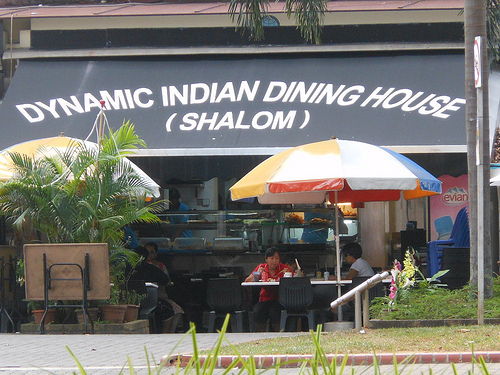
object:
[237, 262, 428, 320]
table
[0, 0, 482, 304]
restaurant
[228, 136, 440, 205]
umbrella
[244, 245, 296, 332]
woman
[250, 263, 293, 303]
shirt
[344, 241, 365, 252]
top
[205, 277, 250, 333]
chair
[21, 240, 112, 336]
table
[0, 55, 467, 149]
sign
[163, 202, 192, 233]
uniform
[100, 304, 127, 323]
pot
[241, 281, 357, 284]
counter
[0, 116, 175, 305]
tree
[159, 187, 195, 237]
worker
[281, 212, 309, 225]
food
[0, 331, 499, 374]
sidewalk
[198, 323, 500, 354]
grass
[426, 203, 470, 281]
seat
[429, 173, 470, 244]
poster